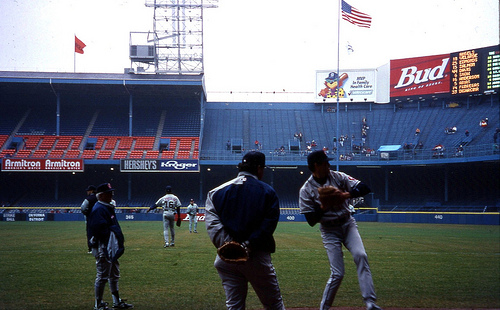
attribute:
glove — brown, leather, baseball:
[209, 237, 284, 287]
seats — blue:
[215, 101, 337, 165]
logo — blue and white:
[114, 159, 203, 176]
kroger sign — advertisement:
[155, 157, 201, 172]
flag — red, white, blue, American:
[341, 0, 371, 28]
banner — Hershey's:
[118, 159, 158, 173]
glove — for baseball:
[210, 231, 266, 275]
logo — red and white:
[2, 155, 82, 170]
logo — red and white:
[389, 57, 454, 97]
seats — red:
[2, 131, 200, 165]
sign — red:
[383, 45, 497, 110]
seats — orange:
[19, 125, 213, 167]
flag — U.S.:
[339, 0, 373, 30]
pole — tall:
[331, 3, 344, 73]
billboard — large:
[389, 53, 451, 97]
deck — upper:
[0, 133, 200, 168]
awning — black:
[2, 63, 203, 95]